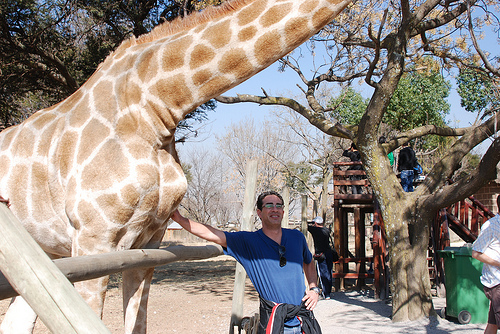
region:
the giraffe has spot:
[125, 144, 165, 224]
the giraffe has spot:
[120, 134, 196, 251]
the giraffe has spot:
[100, 117, 237, 308]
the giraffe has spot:
[120, 170, 181, 214]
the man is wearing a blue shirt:
[222, 187, 359, 329]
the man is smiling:
[189, 166, 318, 333]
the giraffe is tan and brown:
[18, 47, 228, 264]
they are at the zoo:
[18, 15, 489, 326]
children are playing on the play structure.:
[316, 112, 496, 306]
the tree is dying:
[334, 29, 496, 311]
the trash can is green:
[425, 240, 498, 332]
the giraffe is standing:
[14, 12, 289, 332]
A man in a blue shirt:
[219, 176, 367, 331]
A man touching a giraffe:
[119, 148, 350, 308]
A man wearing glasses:
[205, 181, 341, 331]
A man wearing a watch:
[197, 179, 335, 327]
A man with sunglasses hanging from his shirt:
[212, 181, 340, 327]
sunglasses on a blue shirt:
[260, 231, 294, 280]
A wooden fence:
[41, 173, 320, 301]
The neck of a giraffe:
[80, 11, 388, 119]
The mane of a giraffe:
[80, 7, 280, 52]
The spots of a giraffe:
[28, 48, 279, 223]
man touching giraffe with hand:
[139, 4, 372, 333]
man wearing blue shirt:
[224, 182, 347, 329]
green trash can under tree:
[427, 173, 480, 332]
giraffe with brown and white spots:
[89, 36, 247, 264]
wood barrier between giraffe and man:
[54, 182, 256, 332]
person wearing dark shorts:
[457, 204, 497, 330]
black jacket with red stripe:
[222, 164, 352, 329]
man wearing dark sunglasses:
[236, 189, 341, 331]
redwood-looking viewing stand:
[319, 126, 403, 316]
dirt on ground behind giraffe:
[50, 230, 212, 330]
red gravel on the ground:
[150, 304, 190, 326]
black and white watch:
[301, 283, 336, 305]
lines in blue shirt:
[250, 257, 286, 300]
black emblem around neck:
[272, 254, 299, 270]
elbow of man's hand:
[177, 213, 212, 247]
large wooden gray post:
[25, 239, 187, 296]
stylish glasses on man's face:
[261, 199, 306, 218]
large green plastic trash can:
[443, 244, 497, 319]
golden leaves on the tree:
[379, 40, 459, 96]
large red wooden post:
[323, 200, 383, 279]